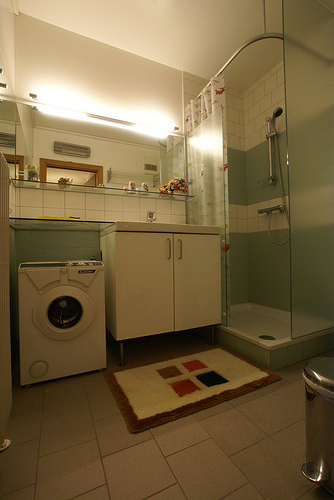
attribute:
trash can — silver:
[299, 351, 330, 498]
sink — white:
[131, 220, 199, 224]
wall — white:
[16, 17, 186, 137]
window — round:
[45, 294, 83, 327]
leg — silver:
[115, 342, 130, 367]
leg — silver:
[205, 322, 218, 349]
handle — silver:
[179, 238, 183, 258]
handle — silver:
[165, 238, 172, 258]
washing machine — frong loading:
[19, 256, 112, 391]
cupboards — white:
[96, 237, 242, 354]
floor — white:
[227, 311, 311, 340]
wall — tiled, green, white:
[187, 24, 332, 322]